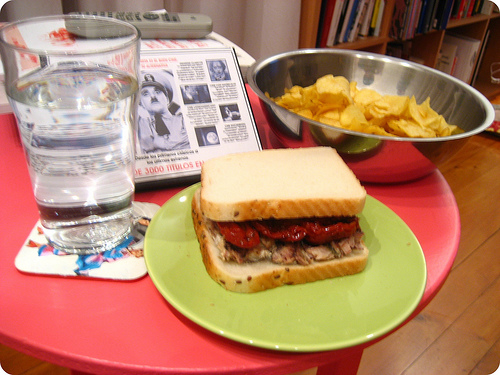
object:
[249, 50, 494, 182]
bowl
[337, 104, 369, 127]
chips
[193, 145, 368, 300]
sandwich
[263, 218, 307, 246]
peppers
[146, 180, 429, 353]
plate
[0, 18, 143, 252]
glass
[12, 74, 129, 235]
water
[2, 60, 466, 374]
table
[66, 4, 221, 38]
remote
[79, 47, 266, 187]
dvd case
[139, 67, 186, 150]
picture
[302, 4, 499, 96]
bookcase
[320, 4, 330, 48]
books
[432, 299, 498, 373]
floor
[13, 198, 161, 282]
coaster